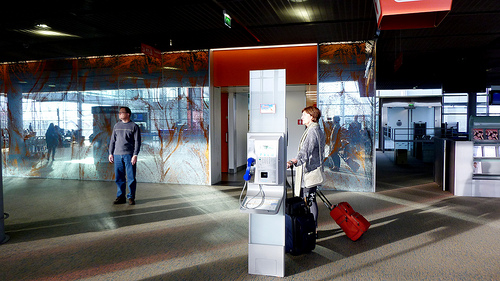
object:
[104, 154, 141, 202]
jeans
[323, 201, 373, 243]
luggage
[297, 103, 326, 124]
hair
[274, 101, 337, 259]
woman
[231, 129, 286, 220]
pay phone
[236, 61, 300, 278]
stand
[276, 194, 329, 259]
suitcase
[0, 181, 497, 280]
floor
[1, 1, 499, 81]
ceiling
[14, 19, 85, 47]
light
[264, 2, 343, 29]
light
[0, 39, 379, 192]
wall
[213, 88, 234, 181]
door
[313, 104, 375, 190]
reflection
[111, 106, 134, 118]
hair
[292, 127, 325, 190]
handbag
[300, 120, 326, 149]
shoulder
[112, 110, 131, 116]
glasses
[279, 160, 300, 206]
handle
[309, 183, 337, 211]
handle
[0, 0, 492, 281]
lobby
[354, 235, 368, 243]
wheels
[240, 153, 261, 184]
handle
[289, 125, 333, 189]
sweater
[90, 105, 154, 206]
man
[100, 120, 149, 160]
sweater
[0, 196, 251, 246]
shadow